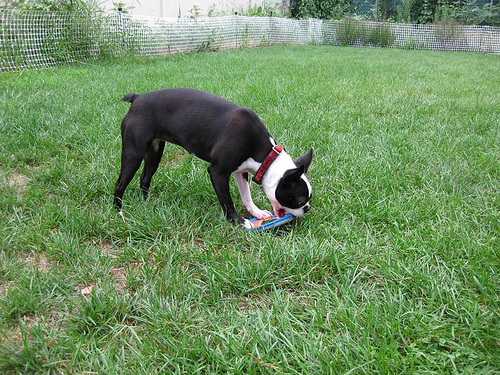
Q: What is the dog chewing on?
A: A frisbee.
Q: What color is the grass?
A: Green.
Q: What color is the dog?
A: Black.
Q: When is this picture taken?
A: During the daytime.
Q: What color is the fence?
A: White.